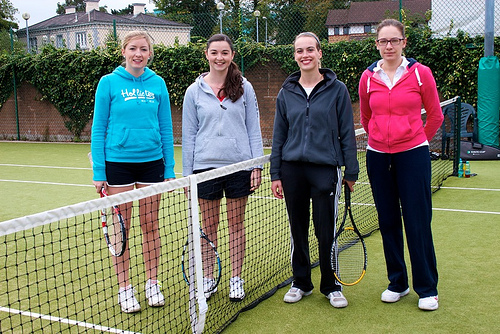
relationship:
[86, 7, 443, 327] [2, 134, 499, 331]
girls on tennis court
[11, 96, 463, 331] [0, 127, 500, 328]
net across court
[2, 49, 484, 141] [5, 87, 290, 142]
vines growing against wall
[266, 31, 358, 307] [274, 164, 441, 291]
girls wearing pants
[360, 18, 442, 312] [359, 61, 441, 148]
girl wearing fleece jacket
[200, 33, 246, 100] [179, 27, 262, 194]
girl wearing grey fleece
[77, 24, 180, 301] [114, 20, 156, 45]
girl with hair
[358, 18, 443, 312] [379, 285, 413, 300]
girl wearing sneaker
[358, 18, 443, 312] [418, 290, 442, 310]
girl wearing sneaker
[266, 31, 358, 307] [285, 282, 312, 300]
girls wearing sneaker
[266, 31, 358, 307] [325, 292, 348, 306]
girls wearing sneaker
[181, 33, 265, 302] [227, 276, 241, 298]
girl wearing sneaker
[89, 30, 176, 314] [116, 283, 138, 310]
girl wearing sneaker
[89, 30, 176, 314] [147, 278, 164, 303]
girl wearing sneaker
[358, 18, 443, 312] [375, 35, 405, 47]
girl wearing glasses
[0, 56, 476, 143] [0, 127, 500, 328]
brick fence near court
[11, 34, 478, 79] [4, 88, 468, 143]
plants growing on wall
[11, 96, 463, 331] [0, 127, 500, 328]
net crossing court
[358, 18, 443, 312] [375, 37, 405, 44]
girl sporting glasses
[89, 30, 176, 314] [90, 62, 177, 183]
girl in pull over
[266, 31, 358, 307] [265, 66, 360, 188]
girls in black jacket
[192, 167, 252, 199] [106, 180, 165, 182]
kites have trim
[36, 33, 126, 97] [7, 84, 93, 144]
ivy hanging over wall